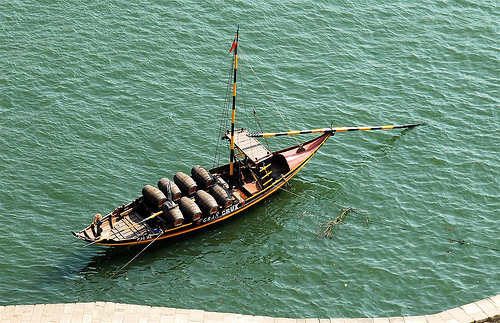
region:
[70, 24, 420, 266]
a brown sailboat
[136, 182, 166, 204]
a large wooden barrel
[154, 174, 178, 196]
a large wooden barrel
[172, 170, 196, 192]
a large wooden barrel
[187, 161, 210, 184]
a large wooden barrel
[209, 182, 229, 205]
a large wooden barrel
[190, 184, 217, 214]
a large wooden barrel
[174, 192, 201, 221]
a large wooden barrel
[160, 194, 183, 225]
a large wooden barrel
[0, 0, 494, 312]
a large body of water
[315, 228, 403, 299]
the water is so green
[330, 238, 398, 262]
the water is so green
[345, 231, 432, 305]
the water is so green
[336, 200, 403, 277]
the water is so green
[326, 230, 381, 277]
the water is so green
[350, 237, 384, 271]
the water is so green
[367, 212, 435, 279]
the water is so green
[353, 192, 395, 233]
the water is so green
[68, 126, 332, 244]
The boat is brown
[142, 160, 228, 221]
Eight barrels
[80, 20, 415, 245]
three black and yellow poles on boat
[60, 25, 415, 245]
boat is on the water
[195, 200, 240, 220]
white writing is on the boat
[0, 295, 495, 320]
brick wall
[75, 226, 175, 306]
boat is tied to wall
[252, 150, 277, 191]
yellow ladder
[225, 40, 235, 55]
red flag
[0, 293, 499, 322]
bricks are white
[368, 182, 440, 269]
The water is calm.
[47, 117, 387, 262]
The boat is wooden.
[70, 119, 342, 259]
The boat has items on it.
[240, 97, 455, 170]
The sail is broken.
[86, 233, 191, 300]
The boat is docked.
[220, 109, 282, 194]
The platform is on the boat.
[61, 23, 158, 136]
The water is blue.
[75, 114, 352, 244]
The boat is brown.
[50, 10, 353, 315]
The boat is in the water.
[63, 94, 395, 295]
No one is on the boat.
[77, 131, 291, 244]
brown boat in green water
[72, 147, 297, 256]
docked brown boat in green water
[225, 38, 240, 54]
red flag at top of pole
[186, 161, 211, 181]
brown barrel on boat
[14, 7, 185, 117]
waves on green water in dock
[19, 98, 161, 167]
waves on green water in dock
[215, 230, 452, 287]
waves on green water in dock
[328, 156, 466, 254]
waves on green water in dock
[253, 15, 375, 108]
waves on green water in dock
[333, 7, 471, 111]
waves on green water in dock